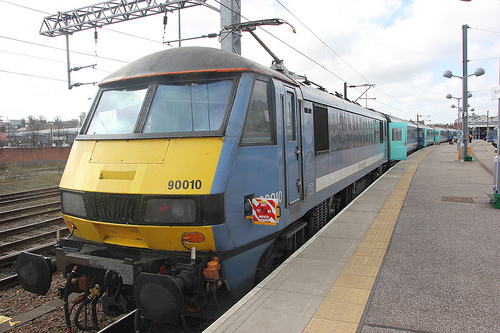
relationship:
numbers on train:
[163, 175, 208, 195] [18, 43, 458, 301]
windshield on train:
[81, 75, 229, 135] [48, 22, 496, 317]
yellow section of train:
[58, 137, 223, 257] [18, 43, 458, 301]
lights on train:
[45, 188, 206, 243] [18, 43, 458, 301]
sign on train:
[248, 198, 281, 228] [18, 43, 458, 301]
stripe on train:
[316, 151, 384, 191] [18, 43, 458, 301]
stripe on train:
[404, 140, 421, 148] [18, 43, 458, 301]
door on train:
[269, 92, 286, 192] [6, 39, 472, 331]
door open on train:
[383, 120, 411, 161] [6, 39, 472, 331]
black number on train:
[166, 180, 201, 190] [60, 46, 462, 328]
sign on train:
[252, 198, 279, 225] [6, 39, 472, 331]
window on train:
[239, 75, 274, 144] [6, 39, 472, 331]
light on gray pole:
[444, 70, 463, 80] [460, 24, 469, 161]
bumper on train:
[135, 269, 182, 331] [6, 39, 472, 331]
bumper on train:
[14, 250, 53, 296] [71, 60, 401, 266]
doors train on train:
[382, 117, 444, 166] [6, 39, 472, 331]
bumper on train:
[15, 250, 52, 294] [6, 39, 472, 331]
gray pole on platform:
[460, 24, 469, 161] [198, 128, 495, 330]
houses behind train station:
[6, 127, 81, 145] [0, 137, 498, 327]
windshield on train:
[81, 75, 239, 135] [6, 39, 472, 331]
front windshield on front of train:
[138, 78, 241, 134] [21, 45, 391, 330]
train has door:
[57, 40, 479, 307] [368, 91, 407, 181]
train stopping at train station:
[14, 44, 466, 332] [197, 139, 497, 333]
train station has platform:
[157, 120, 497, 330] [198, 128, 495, 330]